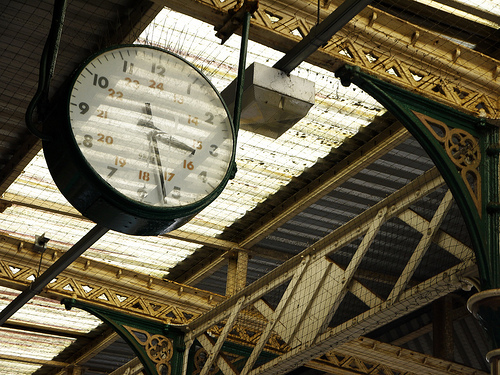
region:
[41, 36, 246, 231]
this is a clock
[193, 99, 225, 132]
a number on the clock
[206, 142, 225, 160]
a number on the clock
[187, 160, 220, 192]
a number on the clock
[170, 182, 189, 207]
a number on the clock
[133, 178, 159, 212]
a number on the clock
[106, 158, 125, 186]
a number on the clock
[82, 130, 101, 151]
a number on the clock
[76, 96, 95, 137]
a number on the clock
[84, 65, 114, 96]
a number on the clock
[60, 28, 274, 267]
a clock that is hanging from the ceiling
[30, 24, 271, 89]
spikes on a clock to prevent birds from standing on it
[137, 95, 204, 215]
the hands of a clock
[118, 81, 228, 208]
hour and minute hands on a clock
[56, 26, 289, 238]
an analog clock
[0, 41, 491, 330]
a net above ground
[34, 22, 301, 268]
a clock at a train station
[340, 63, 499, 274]
green wrought iron molding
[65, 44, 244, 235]
the clock has black and red numbers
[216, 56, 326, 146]
a light fixture on a railing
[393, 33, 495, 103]
Brown colored metal roof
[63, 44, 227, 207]
A big round clock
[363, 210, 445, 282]
A black meshed surface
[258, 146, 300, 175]
A transparent illuminating sheet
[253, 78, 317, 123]
A small grey patch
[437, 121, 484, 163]
A beautiful brown decoration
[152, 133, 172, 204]
A long clock hand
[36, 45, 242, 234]
White and black clock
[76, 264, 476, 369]
A beautifully decorated roof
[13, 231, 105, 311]
A long black rod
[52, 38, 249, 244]
A large circular clock hanging from the ceiling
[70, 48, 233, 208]
The white interior of the large clock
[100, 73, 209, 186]
Small red numbers arranged in a circle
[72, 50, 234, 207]
Large black numbers arranged in a circle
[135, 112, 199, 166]
The hour hand of the clock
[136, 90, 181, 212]
The minute hand of the clock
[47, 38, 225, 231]
The black metal exterior of the clock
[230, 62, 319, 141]
A grey metal structure on the ceiling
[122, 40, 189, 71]
Small black dashes on the clock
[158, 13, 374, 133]
Glass windows on the ceiling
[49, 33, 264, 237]
white and black clock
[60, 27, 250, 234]
clock indicating it's almost 3:30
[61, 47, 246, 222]
black numbers around the circumference of the clock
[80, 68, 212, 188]
small brown numbers around the clock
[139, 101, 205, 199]
two black clock hands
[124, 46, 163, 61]
black tick marks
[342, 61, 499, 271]
black and brown rods in a design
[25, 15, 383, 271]
light coming off the ceiling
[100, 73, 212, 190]
reflections on the face of the clock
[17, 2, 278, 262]
clock hanging from the ceiling